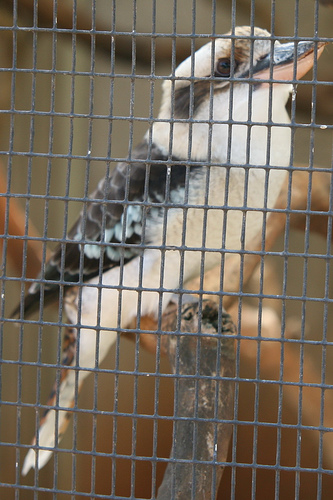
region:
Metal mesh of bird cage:
[1, 2, 326, 498]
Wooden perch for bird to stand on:
[151, 298, 238, 495]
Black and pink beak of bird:
[246, 38, 331, 88]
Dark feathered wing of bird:
[4, 132, 191, 329]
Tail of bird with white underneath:
[9, 319, 97, 475]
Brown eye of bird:
[212, 46, 240, 85]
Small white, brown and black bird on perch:
[0, 19, 325, 481]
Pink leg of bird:
[153, 291, 178, 334]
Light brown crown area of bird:
[161, 25, 268, 76]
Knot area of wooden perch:
[179, 287, 235, 363]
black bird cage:
[1, 0, 101, 135]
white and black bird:
[28, 24, 329, 402]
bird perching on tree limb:
[13, 19, 317, 431]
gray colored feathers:
[86, 184, 183, 248]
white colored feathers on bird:
[213, 113, 283, 192]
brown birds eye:
[214, 57, 236, 81]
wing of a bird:
[10, 134, 147, 329]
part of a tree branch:
[167, 299, 229, 498]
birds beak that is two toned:
[256, 34, 332, 84]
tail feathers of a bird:
[17, 314, 105, 476]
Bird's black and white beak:
[253, 37, 326, 85]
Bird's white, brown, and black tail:
[17, 334, 125, 478]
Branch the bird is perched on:
[135, 311, 246, 497]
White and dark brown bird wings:
[7, 148, 204, 325]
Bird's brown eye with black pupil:
[212, 56, 236, 73]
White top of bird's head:
[158, 33, 232, 88]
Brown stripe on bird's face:
[166, 80, 218, 123]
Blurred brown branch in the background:
[0, 164, 69, 296]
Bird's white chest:
[187, 109, 297, 281]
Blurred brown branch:
[0, 0, 194, 66]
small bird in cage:
[4, 4, 315, 495]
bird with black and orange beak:
[115, 13, 331, 250]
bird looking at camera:
[14, 0, 317, 476]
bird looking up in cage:
[12, 20, 332, 344]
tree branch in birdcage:
[0, 137, 331, 498]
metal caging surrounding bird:
[0, 1, 329, 496]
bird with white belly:
[11, 20, 325, 307]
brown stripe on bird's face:
[5, 25, 331, 474]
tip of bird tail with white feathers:
[9, 16, 328, 472]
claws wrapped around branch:
[44, 5, 332, 326]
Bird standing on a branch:
[117, 212, 252, 346]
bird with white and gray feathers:
[102, 44, 239, 184]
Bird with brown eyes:
[217, 32, 310, 100]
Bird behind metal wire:
[52, 165, 248, 337]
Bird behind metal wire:
[89, 59, 286, 238]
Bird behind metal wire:
[71, 123, 295, 298]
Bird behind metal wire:
[47, 329, 190, 466]